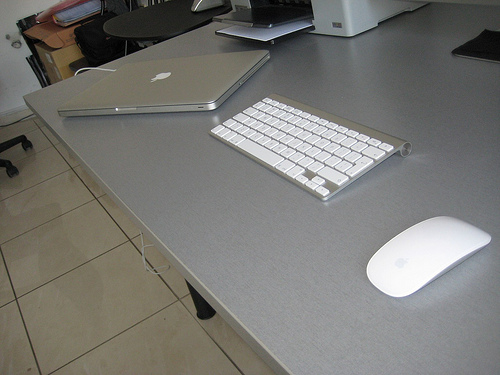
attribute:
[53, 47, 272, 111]
laptop — apple, silver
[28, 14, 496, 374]
table — grey, metal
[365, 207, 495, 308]
mouse — white, apple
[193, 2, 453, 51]
printer — white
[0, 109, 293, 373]
floor — tiled, white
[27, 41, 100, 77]
box — brown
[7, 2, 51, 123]
wall — white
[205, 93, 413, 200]
key — white, silver, for computers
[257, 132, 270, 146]
keyboard — white